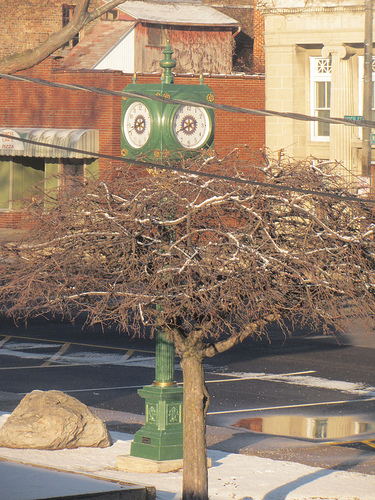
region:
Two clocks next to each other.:
[116, 49, 217, 161]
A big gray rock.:
[2, 385, 119, 452]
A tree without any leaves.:
[12, 147, 360, 496]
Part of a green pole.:
[147, 345, 177, 385]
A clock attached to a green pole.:
[120, 95, 151, 145]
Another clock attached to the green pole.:
[168, 105, 207, 146]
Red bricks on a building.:
[7, 88, 91, 119]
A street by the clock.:
[9, 295, 363, 440]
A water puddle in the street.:
[222, 402, 365, 440]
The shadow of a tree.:
[241, 435, 374, 498]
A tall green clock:
[114, 47, 230, 457]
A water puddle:
[233, 405, 372, 442]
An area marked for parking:
[5, 362, 373, 455]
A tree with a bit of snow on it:
[0, 159, 373, 497]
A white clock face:
[172, 100, 211, 147]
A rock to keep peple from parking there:
[0, 385, 116, 449]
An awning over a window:
[0, 128, 100, 156]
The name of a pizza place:
[0, 130, 27, 152]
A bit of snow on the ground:
[214, 454, 373, 494]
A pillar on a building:
[327, 40, 355, 178]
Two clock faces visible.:
[118, 94, 214, 152]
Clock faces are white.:
[120, 97, 210, 151]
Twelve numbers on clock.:
[170, 101, 207, 149]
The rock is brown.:
[0, 386, 113, 450]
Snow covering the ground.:
[1, 400, 373, 498]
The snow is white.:
[1, 406, 373, 494]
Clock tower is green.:
[115, 35, 216, 465]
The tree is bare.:
[5, 139, 373, 369]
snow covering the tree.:
[85, 146, 370, 275]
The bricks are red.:
[1, 62, 269, 201]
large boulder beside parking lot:
[3, 386, 116, 460]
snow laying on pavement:
[300, 375, 361, 395]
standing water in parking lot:
[234, 405, 372, 451]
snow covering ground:
[223, 463, 306, 498]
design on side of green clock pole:
[159, 401, 182, 426]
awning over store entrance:
[0, 121, 105, 155]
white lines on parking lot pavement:
[210, 363, 366, 408]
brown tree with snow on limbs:
[92, 203, 335, 320]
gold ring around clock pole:
[149, 374, 181, 392]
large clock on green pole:
[120, 96, 158, 156]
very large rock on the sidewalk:
[1, 366, 126, 473]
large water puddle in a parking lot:
[218, 391, 362, 467]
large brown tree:
[34, 149, 346, 491]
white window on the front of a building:
[283, 50, 351, 133]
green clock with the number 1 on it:
[85, 54, 249, 485]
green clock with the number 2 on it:
[70, 64, 258, 473]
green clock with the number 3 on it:
[111, 62, 239, 421]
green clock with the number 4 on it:
[99, 30, 259, 426]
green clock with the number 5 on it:
[115, 27, 218, 468]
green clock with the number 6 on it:
[95, 14, 216, 483]